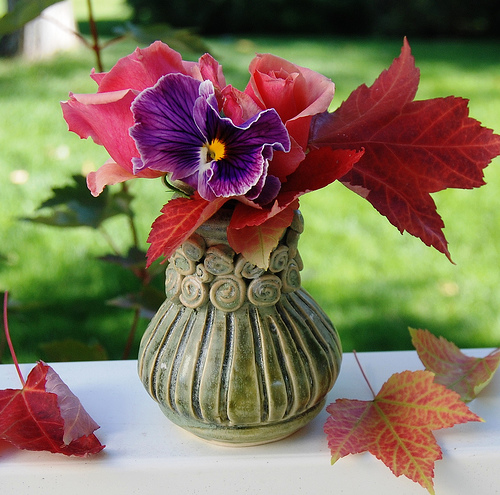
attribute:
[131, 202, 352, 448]
vase — green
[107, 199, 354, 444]
vase — groove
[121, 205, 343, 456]
vase — green, ceramic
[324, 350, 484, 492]
leaf — red, yellow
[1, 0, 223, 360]
plant — purple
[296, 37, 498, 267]
red leaf — large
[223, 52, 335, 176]
rose — pink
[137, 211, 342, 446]
vase — green, decorative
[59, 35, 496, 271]
flowers — colorful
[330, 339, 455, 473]
leaves — green, red, loose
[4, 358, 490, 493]
table — white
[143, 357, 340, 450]
vase — base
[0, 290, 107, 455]
leaf — red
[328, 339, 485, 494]
leaf — veins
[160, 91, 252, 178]
flower — purple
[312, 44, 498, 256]
leaf — red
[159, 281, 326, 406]
vase — small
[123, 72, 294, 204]
flower — purple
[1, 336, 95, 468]
leaf — red